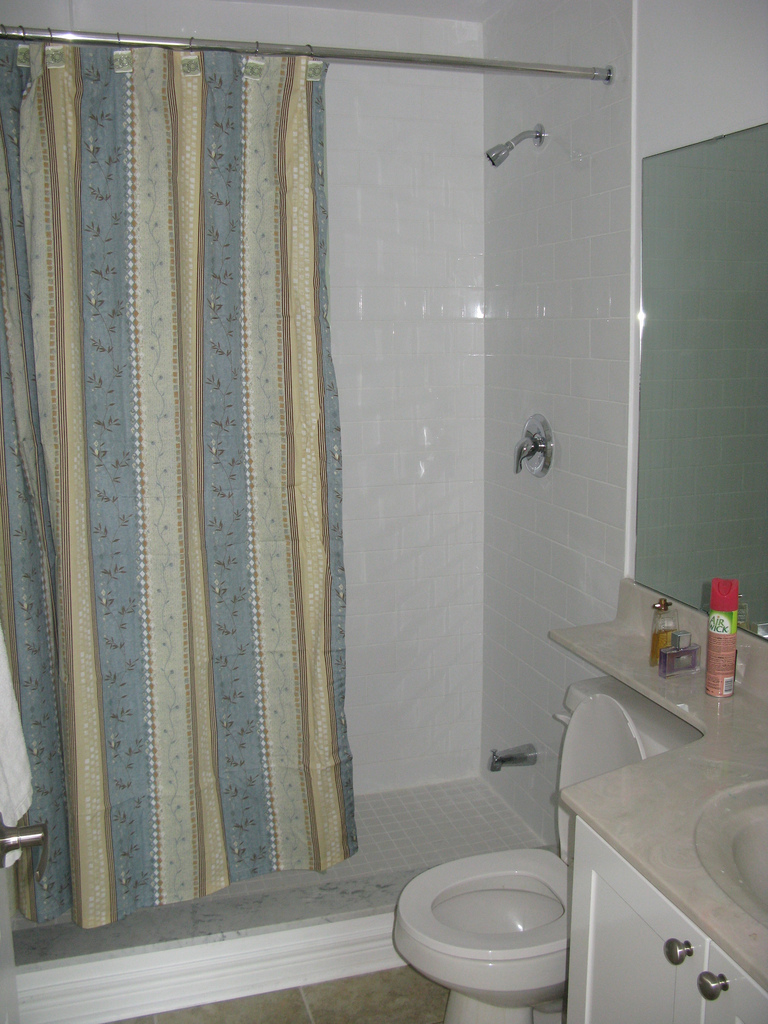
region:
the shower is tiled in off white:
[8, 10, 621, 910]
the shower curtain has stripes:
[6, 22, 359, 924]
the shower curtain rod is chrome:
[6, 20, 620, 92]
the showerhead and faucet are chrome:
[482, 118, 550, 175]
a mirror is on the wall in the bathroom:
[642, 121, 767, 649]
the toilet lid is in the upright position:
[553, 693, 650, 891]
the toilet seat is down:
[399, 845, 570, 965]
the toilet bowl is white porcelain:
[394, 888, 569, 1022]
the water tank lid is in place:
[562, 669, 699, 764]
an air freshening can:
[703, 577, 740, 699]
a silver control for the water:
[516, 416, 554, 480]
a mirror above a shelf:
[633, 121, 766, 646]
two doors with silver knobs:
[564, 815, 766, 1022]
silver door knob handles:
[0, 815, 50, 881]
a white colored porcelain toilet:
[391, 670, 697, 1019]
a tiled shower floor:
[166, 776, 550, 905]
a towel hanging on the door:
[1, 629, 40, 836]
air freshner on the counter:
[697, 564, 750, 702]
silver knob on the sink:
[664, 926, 726, 1002]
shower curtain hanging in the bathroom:
[0, 15, 347, 901]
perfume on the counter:
[643, 587, 681, 682]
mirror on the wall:
[613, 132, 766, 655]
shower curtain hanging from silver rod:
[0, 23, 628, 931]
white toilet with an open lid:
[391, 679, 700, 1021]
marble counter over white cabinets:
[542, 574, 766, 1022]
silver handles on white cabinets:
[560, 812, 767, 1022]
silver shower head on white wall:
[476, 3, 640, 840]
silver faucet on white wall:
[477, 0, 641, 870]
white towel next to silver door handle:
[0, 630, 51, 890]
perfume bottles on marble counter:
[544, 578, 765, 981]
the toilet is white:
[387, 715, 636, 1011]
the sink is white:
[706, 782, 766, 926]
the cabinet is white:
[560, 807, 737, 1020]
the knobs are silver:
[661, 938, 722, 996]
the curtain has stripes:
[0, 47, 373, 878]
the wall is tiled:
[1, 2, 634, 818]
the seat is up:
[384, 691, 647, 1013]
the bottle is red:
[711, 573, 736, 702]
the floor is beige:
[126, 969, 450, 1020]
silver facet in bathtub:
[469, 733, 560, 785]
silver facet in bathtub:
[460, 730, 538, 794]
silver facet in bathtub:
[468, 736, 550, 788]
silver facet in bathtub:
[457, 730, 551, 796]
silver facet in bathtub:
[461, 730, 546, 798]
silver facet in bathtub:
[475, 730, 551, 789]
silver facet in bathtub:
[470, 728, 551, 790]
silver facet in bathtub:
[468, 726, 556, 792]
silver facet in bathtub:
[476, 728, 557, 789]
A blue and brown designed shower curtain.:
[7, 30, 336, 901]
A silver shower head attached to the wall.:
[480, 117, 551, 172]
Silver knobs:
[659, 938, 745, 1004]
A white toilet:
[388, 681, 697, 1018]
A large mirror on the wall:
[630, 126, 766, 635]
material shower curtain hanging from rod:
[2, 41, 362, 931]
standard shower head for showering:
[485, 123, 548, 173]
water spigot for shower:
[479, 741, 541, 777]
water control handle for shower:
[510, 409, 559, 484]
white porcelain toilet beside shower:
[389, 668, 708, 1022]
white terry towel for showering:
[0, 617, 38, 829]